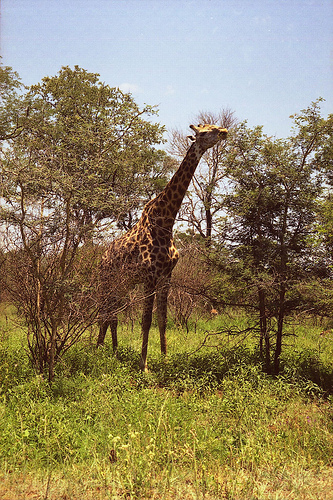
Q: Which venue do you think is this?
A: This is a field.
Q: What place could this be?
A: It is a field.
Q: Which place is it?
A: It is a field.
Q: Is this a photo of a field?
A: Yes, it is showing a field.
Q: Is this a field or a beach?
A: It is a field.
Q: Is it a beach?
A: No, it is a field.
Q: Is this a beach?
A: No, it is a field.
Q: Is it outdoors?
A: Yes, it is outdoors.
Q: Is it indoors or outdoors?
A: It is outdoors.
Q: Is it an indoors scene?
A: No, it is outdoors.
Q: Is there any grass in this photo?
A: Yes, there is grass.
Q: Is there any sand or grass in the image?
A: Yes, there is grass.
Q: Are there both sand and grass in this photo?
A: No, there is grass but no sand.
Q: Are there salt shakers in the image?
A: No, there are no salt shakers.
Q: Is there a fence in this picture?
A: No, there are no fences.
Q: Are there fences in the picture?
A: No, there are no fences.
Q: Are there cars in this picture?
A: No, there are no cars.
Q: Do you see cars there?
A: No, there are no cars.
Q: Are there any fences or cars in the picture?
A: No, there are no cars or fences.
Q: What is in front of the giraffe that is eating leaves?
A: The tree is in front of the giraffe.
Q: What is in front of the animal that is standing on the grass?
A: The tree is in front of the giraffe.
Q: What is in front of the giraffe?
A: The tree is in front of the giraffe.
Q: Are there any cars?
A: No, there are no cars.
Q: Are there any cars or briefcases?
A: No, there are no cars or briefcases.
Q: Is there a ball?
A: No, there are no balls.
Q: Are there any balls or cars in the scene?
A: No, there are no balls or cars.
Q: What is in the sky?
A: The clouds are in the sky.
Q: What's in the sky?
A: The clouds are in the sky.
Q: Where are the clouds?
A: The clouds are in the sky.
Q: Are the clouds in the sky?
A: Yes, the clouds are in the sky.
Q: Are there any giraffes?
A: Yes, there is a giraffe.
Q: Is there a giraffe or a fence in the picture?
A: Yes, there is a giraffe.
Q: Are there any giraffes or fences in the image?
A: Yes, there is a giraffe.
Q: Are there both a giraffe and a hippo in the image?
A: No, there is a giraffe but no hippoes.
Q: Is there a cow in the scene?
A: No, there are no cows.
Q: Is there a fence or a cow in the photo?
A: No, there are no cows or fences.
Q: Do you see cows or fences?
A: No, there are no cows or fences.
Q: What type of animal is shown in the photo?
A: The animal is a giraffe.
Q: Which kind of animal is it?
A: The animal is a giraffe.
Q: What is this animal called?
A: This is a giraffe.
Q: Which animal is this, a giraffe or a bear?
A: This is a giraffe.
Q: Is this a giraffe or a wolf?
A: This is a giraffe.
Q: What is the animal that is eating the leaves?
A: The animal is a giraffe.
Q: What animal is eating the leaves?
A: The animal is a giraffe.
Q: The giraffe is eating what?
A: The giraffe is eating leaves.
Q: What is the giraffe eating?
A: The giraffe is eating leaves.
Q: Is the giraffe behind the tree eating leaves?
A: Yes, the giraffe is eating leaves.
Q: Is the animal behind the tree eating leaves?
A: Yes, the giraffe is eating leaves.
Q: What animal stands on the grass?
A: The giraffe stands on the grass.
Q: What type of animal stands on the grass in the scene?
A: The animal is a giraffe.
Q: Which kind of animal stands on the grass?
A: The animal is a giraffe.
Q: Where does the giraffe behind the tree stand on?
A: The giraffe stands on the grass.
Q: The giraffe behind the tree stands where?
A: The giraffe stands on the grass.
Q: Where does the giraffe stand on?
A: The giraffe stands on the grass.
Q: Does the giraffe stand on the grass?
A: Yes, the giraffe stands on the grass.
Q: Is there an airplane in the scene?
A: No, there are no airplanes.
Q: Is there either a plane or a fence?
A: No, there are no airplanes or fences.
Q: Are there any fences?
A: No, there are no fences.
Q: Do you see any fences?
A: No, there are no fences.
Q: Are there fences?
A: No, there are no fences.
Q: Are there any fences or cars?
A: No, there are no fences or cars.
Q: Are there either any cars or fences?
A: No, there are no fences or cars.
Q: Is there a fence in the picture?
A: No, there are no fences.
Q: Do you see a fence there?
A: No, there are no fences.